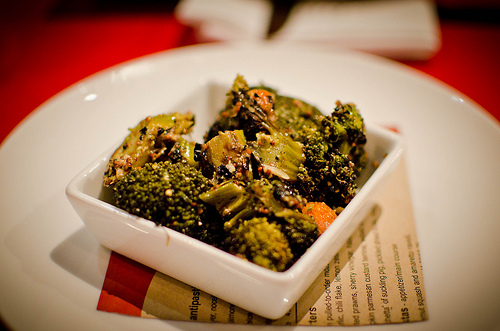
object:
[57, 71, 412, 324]
bowl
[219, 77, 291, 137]
veggie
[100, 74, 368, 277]
broccoli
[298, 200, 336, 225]
small carrot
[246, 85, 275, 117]
round carrot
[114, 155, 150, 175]
spices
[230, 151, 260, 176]
spices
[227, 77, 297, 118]
spices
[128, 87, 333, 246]
vegetables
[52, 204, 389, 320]
bowl shadow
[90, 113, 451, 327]
paper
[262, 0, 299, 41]
knife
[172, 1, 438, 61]
towel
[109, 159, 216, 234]
floret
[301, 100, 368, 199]
floret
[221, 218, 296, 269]
floret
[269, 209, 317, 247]
floret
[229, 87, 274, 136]
floret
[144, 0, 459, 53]
white towel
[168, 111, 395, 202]
floret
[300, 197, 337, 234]
carrot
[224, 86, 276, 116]
carrot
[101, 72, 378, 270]
veggie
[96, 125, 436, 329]
paper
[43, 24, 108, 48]
table cloth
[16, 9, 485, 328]
table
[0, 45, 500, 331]
plate